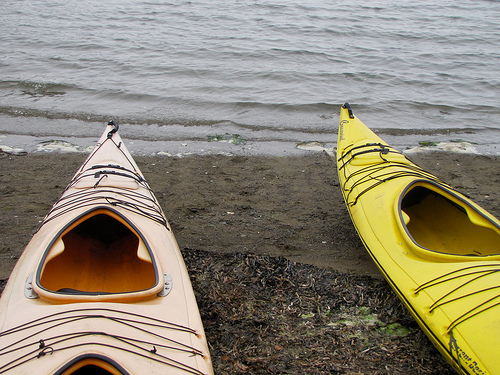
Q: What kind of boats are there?
A: Kayaks.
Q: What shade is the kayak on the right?
A: Yellow.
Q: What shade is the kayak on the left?
A: Tan.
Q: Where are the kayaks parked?
A: Shore.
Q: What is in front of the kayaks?
A: Body of water.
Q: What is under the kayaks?
A: Mud.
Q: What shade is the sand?
A: Dark brown.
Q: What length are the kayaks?
A: Long.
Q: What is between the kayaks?
A: Seaweed and other debris.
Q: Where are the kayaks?
A: On the shore.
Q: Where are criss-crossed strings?
A: On both kayaks.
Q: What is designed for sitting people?
A: Holes in kayaks.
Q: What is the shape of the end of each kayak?
A: Pointed.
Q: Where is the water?
A: Top of the photo.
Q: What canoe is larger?
A: The white one.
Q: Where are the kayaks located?
A: Shore.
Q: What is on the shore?
A: Waves.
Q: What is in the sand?
A: Dead leaves.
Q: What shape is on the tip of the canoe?
A: Triangle.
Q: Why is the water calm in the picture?
A: No tide.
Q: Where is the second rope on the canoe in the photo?
A: Rope on the yellow canoe.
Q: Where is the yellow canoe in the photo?
A: Far right near the water.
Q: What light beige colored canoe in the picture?
A: Light beige canoe with rope.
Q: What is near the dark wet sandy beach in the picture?
A: Two canoes.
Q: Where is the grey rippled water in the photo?
A: The ocean.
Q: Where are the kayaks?
A: On the beach.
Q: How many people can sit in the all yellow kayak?
A: One.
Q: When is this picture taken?
A: Day time.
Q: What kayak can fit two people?
A: White.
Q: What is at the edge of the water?
A: Kayaks.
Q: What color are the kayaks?
A: White and yellow.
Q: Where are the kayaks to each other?
A: Side by side.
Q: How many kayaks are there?
A: Two.